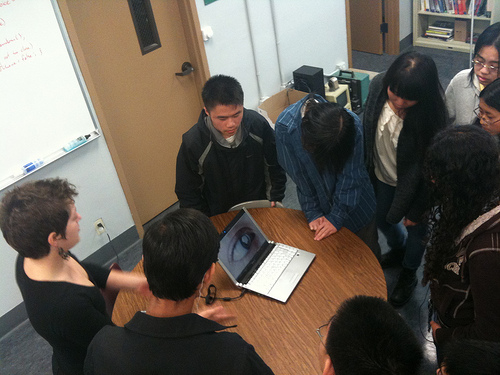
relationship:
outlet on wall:
[92, 219, 108, 239] [0, 2, 135, 321]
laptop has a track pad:
[211, 206, 317, 305] [269, 250, 316, 305]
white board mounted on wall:
[0, 0, 103, 193] [0, 2, 135, 321]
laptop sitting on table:
[211, 206, 317, 305] [111, 205, 388, 374]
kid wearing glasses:
[443, 23, 499, 126] [470, 56, 498, 73]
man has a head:
[82, 208, 276, 374] [140, 206, 220, 304]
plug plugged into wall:
[97, 223, 103, 230] [0, 2, 135, 321]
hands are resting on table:
[308, 214, 337, 242] [111, 205, 388, 374]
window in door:
[128, 0, 163, 57] [55, 2, 203, 228]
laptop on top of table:
[211, 206, 317, 305] [111, 205, 388, 374]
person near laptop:
[2, 177, 236, 373] [211, 206, 317, 305]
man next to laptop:
[173, 73, 287, 219] [211, 206, 317, 305]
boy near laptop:
[275, 91, 382, 258] [211, 206, 317, 305]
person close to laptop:
[423, 123, 500, 363] [211, 206, 317, 305]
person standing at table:
[2, 177, 236, 373] [111, 205, 388, 374]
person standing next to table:
[423, 123, 500, 363] [111, 205, 388, 374]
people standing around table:
[2, 24, 499, 374] [111, 205, 388, 374]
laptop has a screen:
[211, 206, 317, 305] [213, 211, 264, 277]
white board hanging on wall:
[0, 0, 103, 193] [0, 2, 135, 321]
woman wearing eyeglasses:
[469, 75, 499, 141] [471, 104, 499, 125]